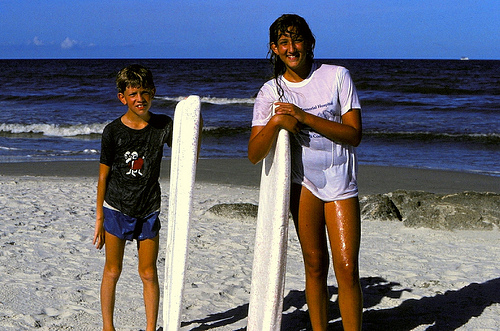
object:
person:
[92, 63, 203, 330]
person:
[247, 13, 364, 331]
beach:
[373, 63, 498, 329]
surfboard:
[160, 93, 202, 329]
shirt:
[98, 112, 173, 218]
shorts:
[103, 207, 162, 241]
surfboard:
[246, 102, 291, 330]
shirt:
[250, 62, 362, 201]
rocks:
[372, 221, 475, 260]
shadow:
[361, 265, 500, 328]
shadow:
[156, 258, 339, 331]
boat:
[459, 54, 470, 61]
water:
[370, 63, 488, 156]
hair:
[260, 16, 328, 36]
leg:
[289, 183, 332, 330]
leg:
[324, 196, 365, 330]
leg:
[100, 230, 124, 329]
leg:
[136, 231, 161, 330]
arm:
[322, 122, 359, 135]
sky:
[0, 0, 499, 59]